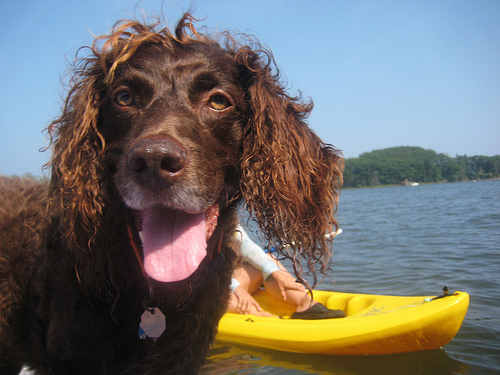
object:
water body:
[204, 175, 500, 375]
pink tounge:
[142, 212, 210, 285]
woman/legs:
[224, 251, 312, 315]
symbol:
[134, 303, 170, 341]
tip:
[136, 256, 203, 285]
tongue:
[133, 206, 214, 285]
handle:
[438, 281, 452, 295]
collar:
[110, 221, 225, 342]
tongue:
[142, 206, 208, 283]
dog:
[0, 7, 350, 373]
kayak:
[216, 279, 468, 357]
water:
[201, 175, 497, 374]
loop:
[140, 293, 160, 317]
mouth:
[115, 180, 222, 283]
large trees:
[392, 148, 446, 183]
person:
[225, 221, 344, 317]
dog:
[0, 0, 348, 375]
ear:
[233, 35, 348, 298]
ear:
[39, 50, 125, 317]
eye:
[110, 80, 142, 120]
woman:
[228, 219, 313, 321]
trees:
[430, 153, 449, 182]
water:
[328, 177, 495, 283]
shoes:
[288, 297, 343, 319]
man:
[226, 218, 345, 318]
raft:
[214, 280, 470, 355]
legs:
[228, 252, 314, 314]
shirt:
[226, 224, 283, 291]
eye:
[200, 85, 230, 120]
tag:
[142, 301, 165, 341]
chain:
[119, 250, 226, 340]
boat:
[213, 266, 470, 352]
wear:
[288, 300, 348, 319]